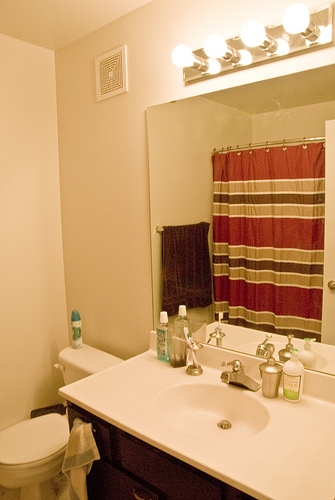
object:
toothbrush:
[183, 326, 198, 368]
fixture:
[220, 358, 262, 392]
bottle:
[156, 310, 174, 363]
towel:
[61, 417, 100, 498]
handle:
[92, 426, 96, 433]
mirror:
[143, 60, 335, 376]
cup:
[166, 323, 187, 367]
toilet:
[1, 329, 123, 497]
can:
[69, 308, 82, 348]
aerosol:
[71, 308, 83, 349]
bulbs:
[239, 17, 278, 55]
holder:
[186, 341, 203, 376]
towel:
[162, 219, 214, 317]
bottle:
[282, 348, 304, 403]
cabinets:
[61, 399, 176, 497]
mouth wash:
[155, 309, 171, 363]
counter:
[58, 347, 334, 498]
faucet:
[220, 359, 261, 391]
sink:
[155, 382, 269, 437]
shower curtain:
[209, 141, 324, 344]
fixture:
[183, 3, 335, 86]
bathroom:
[0, 0, 335, 500]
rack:
[156, 227, 167, 234]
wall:
[148, 108, 218, 330]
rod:
[210, 137, 326, 158]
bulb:
[170, 44, 209, 73]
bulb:
[202, 33, 243, 67]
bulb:
[282, 2, 320, 47]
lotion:
[283, 372, 301, 401]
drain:
[217, 418, 232, 429]